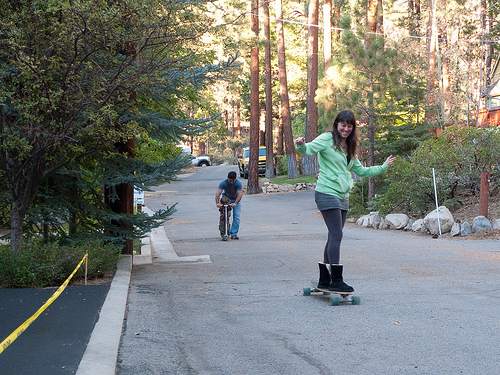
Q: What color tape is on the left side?
A: Yellow.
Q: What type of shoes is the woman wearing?
A: Boots.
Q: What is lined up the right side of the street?
A: Rocks.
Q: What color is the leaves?
A: Green.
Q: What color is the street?
A: Gray.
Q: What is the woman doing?
A: Skateboarding.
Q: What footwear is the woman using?
A: Boots.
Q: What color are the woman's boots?
A: Black.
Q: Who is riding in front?
A: The woman.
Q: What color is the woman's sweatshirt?
A: Green.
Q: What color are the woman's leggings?
A: Grey.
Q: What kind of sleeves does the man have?
A: Short sleeves.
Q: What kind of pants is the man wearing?
A: Jeans.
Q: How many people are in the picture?
A: Two.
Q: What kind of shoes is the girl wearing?
A: Boots.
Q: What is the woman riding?
A: A skateboard.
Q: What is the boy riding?
A: A scooter.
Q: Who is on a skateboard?
A: A woman.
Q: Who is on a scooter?
A: A boy.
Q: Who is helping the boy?
A: A man.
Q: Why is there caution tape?
A: New pavement.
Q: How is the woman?
A: Happy.